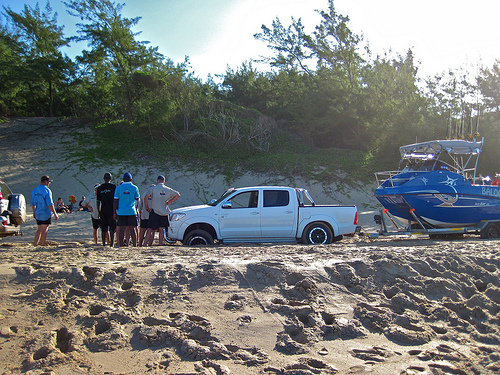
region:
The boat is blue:
[375, 128, 497, 235]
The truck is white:
[164, 187, 361, 252]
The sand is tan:
[3, 131, 495, 372]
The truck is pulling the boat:
[163, 139, 495, 248]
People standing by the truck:
[84, 168, 181, 245]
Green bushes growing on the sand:
[6, 7, 486, 175]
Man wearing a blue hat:
[119, 171, 138, 186]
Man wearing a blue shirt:
[113, 171, 148, 221]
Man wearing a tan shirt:
[142, 174, 179, 216]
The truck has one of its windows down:
[168, 173, 361, 248]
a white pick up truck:
[167, 185, 359, 247]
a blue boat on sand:
[373, 140, 499, 239]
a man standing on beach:
[114, 171, 140, 244]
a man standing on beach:
[32, 174, 58, 243]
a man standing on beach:
[94, 172, 118, 245]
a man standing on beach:
[143, 174, 179, 248]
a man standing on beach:
[84, 181, 102, 244]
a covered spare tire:
[8, 192, 25, 225]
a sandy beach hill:
[4, 245, 499, 372]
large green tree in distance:
[64, 0, 171, 132]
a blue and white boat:
[370, 129, 498, 245]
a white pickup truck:
[171, 186, 366, 245]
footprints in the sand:
[62, 260, 146, 350]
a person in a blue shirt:
[117, 173, 143, 217]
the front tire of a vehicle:
[187, 225, 212, 252]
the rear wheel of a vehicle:
[299, 224, 336, 250]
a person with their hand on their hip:
[147, 172, 179, 227]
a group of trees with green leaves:
[270, 67, 410, 123]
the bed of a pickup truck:
[298, 185, 358, 216]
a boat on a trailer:
[365, 186, 499, 246]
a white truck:
[175, 172, 359, 243]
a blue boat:
[375, 137, 498, 232]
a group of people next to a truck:
[78, 165, 183, 246]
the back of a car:
[0, 182, 27, 237]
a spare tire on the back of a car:
[7, 187, 29, 227]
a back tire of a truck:
[301, 219, 337, 252]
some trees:
[88, 9, 281, 148]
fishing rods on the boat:
[445, 78, 486, 146]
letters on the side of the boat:
[478, 187, 499, 197]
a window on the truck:
[262, 187, 290, 207]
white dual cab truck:
[165, 185, 357, 243]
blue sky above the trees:
[2, 0, 499, 107]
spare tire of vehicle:
[10, 191, 25, 223]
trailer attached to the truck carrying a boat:
[358, 207, 497, 240]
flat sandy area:
[3, 210, 499, 370]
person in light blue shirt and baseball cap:
[113, 171, 140, 245]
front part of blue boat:
[374, 138, 497, 224]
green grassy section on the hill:
[59, 97, 401, 189]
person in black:
[94, 172, 115, 245]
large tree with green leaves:
[65, 1, 184, 129]